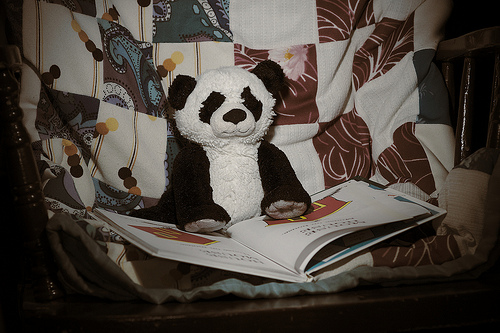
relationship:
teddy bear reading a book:
[130, 59, 310, 235] [85, 174, 449, 283]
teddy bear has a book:
[130, 59, 310, 235] [85, 174, 449, 283]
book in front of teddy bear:
[85, 174, 449, 283] [130, 59, 310, 235]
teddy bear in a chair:
[130, 59, 310, 235] [0, 1, 499, 332]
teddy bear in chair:
[130, 59, 310, 235] [0, 1, 499, 332]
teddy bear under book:
[130, 59, 310, 235] [85, 174, 449, 283]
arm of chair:
[2, 44, 50, 263] [0, 1, 499, 332]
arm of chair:
[434, 26, 499, 168] [0, 1, 499, 332]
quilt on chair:
[0, 0, 499, 306] [0, 1, 499, 332]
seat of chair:
[13, 274, 499, 332] [0, 1, 499, 332]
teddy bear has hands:
[130, 59, 310, 235] [167, 186, 312, 234]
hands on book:
[167, 186, 312, 234] [85, 174, 449, 283]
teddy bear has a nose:
[130, 59, 310, 235] [223, 110, 247, 126]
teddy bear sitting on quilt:
[130, 59, 310, 235] [0, 0, 499, 306]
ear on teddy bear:
[167, 73, 198, 110] [130, 59, 310, 235]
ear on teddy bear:
[248, 59, 285, 97] [130, 59, 310, 235]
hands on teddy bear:
[167, 186, 312, 234] [130, 59, 310, 235]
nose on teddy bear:
[223, 110, 247, 126] [130, 59, 310, 235]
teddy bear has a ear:
[130, 59, 310, 235] [167, 73, 198, 110]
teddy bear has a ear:
[130, 59, 310, 235] [248, 59, 285, 97]